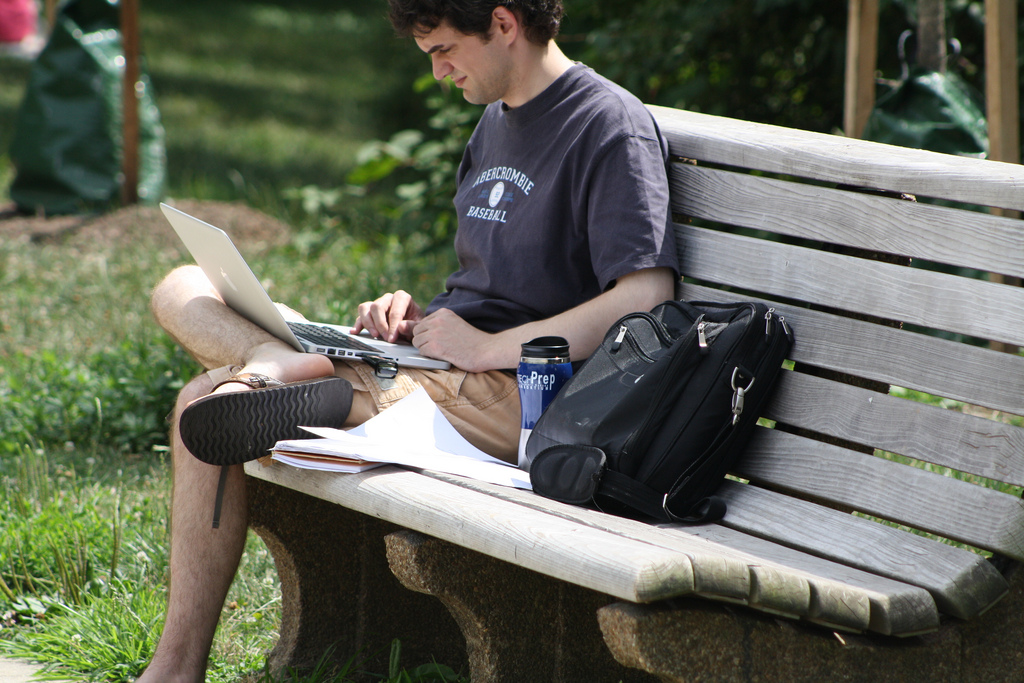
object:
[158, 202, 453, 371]
lap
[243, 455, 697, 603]
wood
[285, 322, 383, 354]
keyboard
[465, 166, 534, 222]
design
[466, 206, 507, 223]
name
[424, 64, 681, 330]
man's t-shirt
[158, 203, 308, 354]
lid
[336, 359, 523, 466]
man's lap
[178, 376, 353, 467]
sandal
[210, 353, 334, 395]
foot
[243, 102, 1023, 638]
bench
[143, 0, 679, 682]
man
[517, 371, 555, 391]
lettering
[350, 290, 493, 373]
man's hands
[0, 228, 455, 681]
grass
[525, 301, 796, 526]
bag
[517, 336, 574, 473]
coffee mug